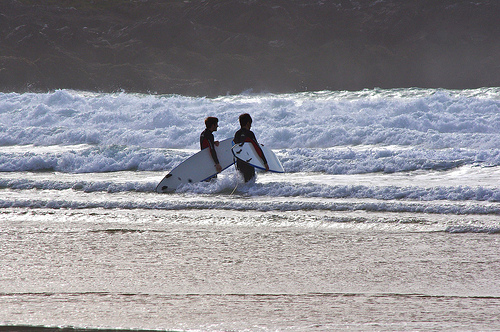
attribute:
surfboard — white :
[225, 135, 287, 173]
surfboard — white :
[152, 132, 239, 194]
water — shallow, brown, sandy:
[5, 224, 498, 329]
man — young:
[197, 114, 223, 182]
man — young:
[232, 112, 269, 182]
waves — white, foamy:
[1, 87, 498, 173]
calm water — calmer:
[4, 226, 499, 330]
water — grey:
[6, 0, 498, 137]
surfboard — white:
[233, 141, 284, 173]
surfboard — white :
[230, 142, 285, 172]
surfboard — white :
[153, 135, 238, 190]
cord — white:
[223, 165, 275, 207]